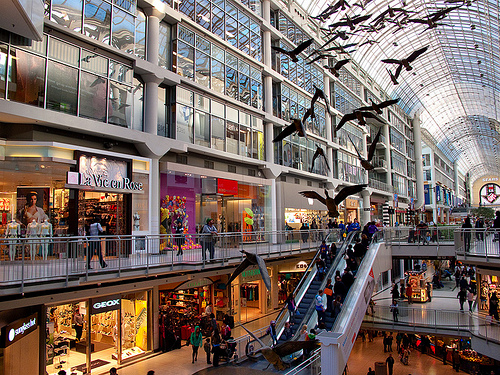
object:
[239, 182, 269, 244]
window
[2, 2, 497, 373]
shopping mall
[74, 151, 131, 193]
sign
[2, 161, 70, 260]
window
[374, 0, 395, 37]
models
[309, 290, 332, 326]
people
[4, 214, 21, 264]
mannequin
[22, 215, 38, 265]
mannequin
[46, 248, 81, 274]
floor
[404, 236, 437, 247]
floor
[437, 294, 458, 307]
floor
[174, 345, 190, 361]
floor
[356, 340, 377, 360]
floor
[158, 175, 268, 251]
window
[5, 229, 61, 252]
rail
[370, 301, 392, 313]
railings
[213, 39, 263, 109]
reflection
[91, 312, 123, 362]
mirror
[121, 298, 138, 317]
lights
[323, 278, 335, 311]
people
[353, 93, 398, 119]
bird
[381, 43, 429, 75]
bird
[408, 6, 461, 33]
bird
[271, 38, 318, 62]
bird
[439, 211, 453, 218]
ground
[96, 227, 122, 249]
railing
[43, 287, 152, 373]
store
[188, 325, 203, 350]
green hoodie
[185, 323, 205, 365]
customer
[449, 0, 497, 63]
roof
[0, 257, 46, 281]
elevated walkway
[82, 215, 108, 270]
person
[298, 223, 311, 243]
person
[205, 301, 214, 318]
woman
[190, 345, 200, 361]
pants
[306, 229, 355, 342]
flock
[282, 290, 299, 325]
people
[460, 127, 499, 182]
glass dome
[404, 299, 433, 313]
railing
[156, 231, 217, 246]
railing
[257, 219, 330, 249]
walkway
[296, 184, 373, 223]
birds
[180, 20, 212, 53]
sky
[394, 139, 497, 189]
atrium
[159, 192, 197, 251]
display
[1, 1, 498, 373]
mall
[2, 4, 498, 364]
picture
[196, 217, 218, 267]
woman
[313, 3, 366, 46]
mobile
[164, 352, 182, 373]
first floor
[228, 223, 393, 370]
escalator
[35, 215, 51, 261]
mannequins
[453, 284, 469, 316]
shopper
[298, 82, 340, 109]
geese